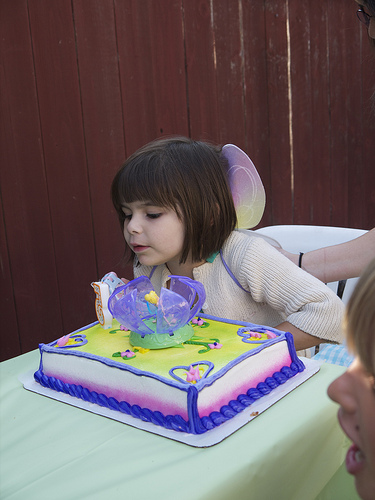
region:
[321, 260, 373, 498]
the face of a child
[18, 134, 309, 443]
a girl looking at her birthday cake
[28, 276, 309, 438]
a birthday cake with icing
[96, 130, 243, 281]
the head of a girl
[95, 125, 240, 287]
a girl with black hair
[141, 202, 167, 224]
the eye of a girl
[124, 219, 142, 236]
the nose of a girl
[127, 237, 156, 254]
the mouth of a girl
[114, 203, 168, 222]
the eyes of a girl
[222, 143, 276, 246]
colorful nylon fairy wings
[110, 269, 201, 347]
a purple and green cake topper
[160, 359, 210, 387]
purple hearts with pink flowers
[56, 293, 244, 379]
yellow top color with pink flowers and green stems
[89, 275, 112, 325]
a birthday candle for a 5th birthday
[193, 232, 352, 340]
little girl wears a white sweater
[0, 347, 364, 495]
light mint green table cloth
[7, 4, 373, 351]
redwood colored wood wall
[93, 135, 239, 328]
little girl leans in to blow out candle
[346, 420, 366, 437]
a birthmark over the top lip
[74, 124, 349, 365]
little girl sitting at table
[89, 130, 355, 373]
little girl looking at cake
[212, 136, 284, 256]
little girl wearing wings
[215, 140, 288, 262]
wings on girl is purple an dyellow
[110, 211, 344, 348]
little girl wearing sweater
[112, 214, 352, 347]
little girls sweater is cream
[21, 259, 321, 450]
birthday cake sitting on table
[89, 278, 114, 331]
candle on birthday cake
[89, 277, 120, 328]
candle is number 5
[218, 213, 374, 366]
girl sitting in white chair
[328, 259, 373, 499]
Boy with mole on face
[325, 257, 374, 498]
Boy with blonde hair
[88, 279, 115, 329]
Orange and white candle with the number 5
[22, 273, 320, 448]
Cake with white, pink, purple and green frosting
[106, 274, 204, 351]
Purple and green cake topper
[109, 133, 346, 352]
Girl wearing fairy wings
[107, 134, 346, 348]
Girl celebrating her birthday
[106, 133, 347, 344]
Girl looking at birthday cake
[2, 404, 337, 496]
Light green table cloth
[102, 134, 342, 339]
Girl wearing cream colored sweater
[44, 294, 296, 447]
the cake is colorful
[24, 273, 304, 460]
a cake on the table